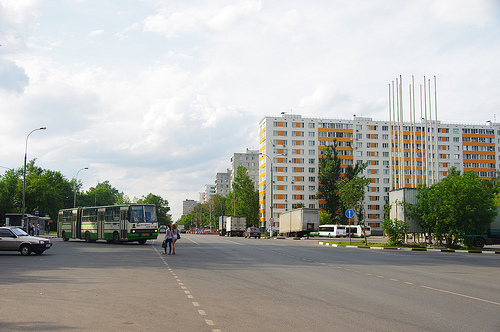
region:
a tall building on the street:
[257, 72, 497, 249]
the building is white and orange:
[251, 103, 498, 233]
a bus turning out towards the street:
[51, 197, 163, 247]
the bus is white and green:
[62, 198, 161, 243]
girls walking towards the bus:
[162, 217, 179, 255]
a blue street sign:
[340, 204, 362, 244]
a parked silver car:
[0, 219, 60, 263]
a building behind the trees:
[385, 71, 447, 244]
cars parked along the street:
[182, 210, 271, 247]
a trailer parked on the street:
[270, 203, 319, 235]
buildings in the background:
[182, 110, 399, 247]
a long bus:
[52, 199, 162, 254]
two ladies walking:
[159, 220, 184, 257]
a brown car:
[1, 220, 64, 273]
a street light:
[13, 122, 50, 224]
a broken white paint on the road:
[153, 263, 218, 330]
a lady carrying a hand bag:
[160, 220, 174, 259]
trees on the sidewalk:
[188, 173, 270, 233]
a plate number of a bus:
[140, 230, 152, 237]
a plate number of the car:
[43, 243, 51, 248]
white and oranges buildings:
[263, 115, 497, 232]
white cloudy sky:
[8, 0, 499, 205]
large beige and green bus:
[54, 205, 156, 245]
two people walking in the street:
[160, 223, 183, 256]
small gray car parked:
[0, 218, 49, 250]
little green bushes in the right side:
[387, 173, 498, 253]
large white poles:
[384, 71, 439, 187]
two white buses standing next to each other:
[319, 218, 370, 238]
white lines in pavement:
[147, 235, 221, 330]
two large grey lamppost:
[19, 125, 92, 250]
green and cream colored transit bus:
[55, 200, 169, 248]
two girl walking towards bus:
[134, 204, 192, 256]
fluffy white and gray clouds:
[2, 6, 471, 168]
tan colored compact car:
[2, 222, 59, 257]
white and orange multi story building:
[258, 109, 498, 240]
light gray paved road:
[67, 222, 496, 327]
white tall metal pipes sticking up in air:
[385, 72, 442, 219]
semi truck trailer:
[278, 206, 325, 241]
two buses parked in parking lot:
[316, 216, 374, 243]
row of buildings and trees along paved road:
[176, 112, 286, 233]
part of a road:
[360, 276, 383, 301]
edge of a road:
[131, 242, 166, 291]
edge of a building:
[265, 131, 280, 176]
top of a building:
[316, 120, 338, 121]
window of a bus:
[136, 214, 148, 216]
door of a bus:
[101, 215, 114, 252]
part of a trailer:
[290, 218, 302, 220]